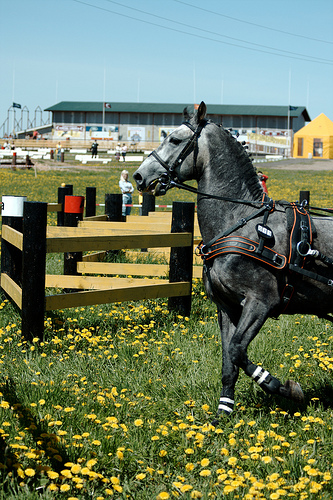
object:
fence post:
[20, 199, 47, 339]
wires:
[177, 0, 333, 47]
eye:
[167, 135, 182, 147]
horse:
[132, 99, 333, 424]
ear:
[182, 106, 193, 123]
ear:
[194, 100, 208, 123]